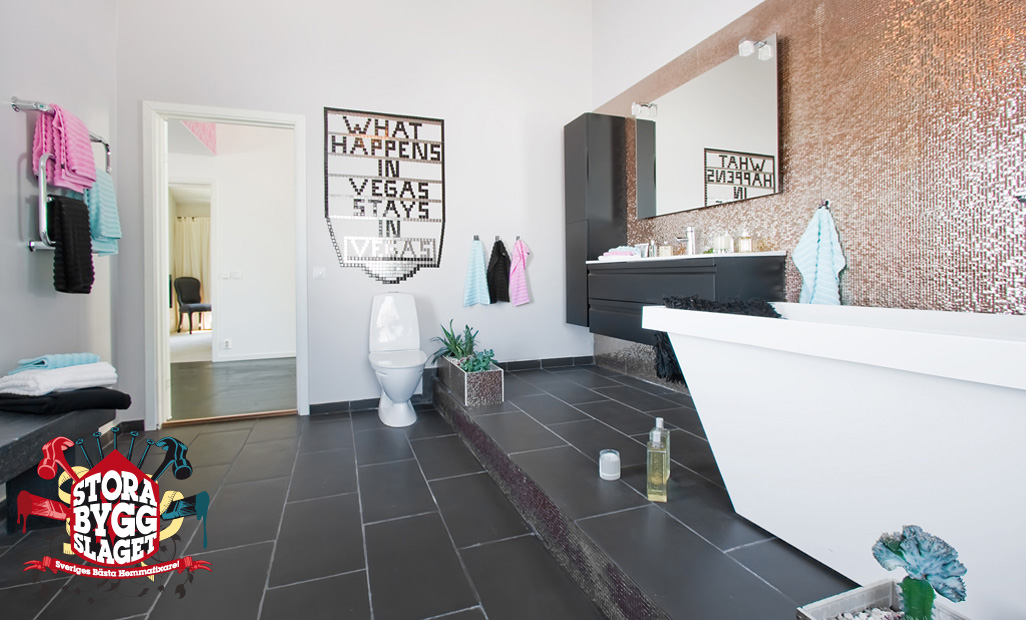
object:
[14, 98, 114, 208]
towel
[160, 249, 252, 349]
chair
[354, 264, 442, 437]
toilet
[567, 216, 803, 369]
vanity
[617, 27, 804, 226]
mirror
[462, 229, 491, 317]
hand towel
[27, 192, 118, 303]
towel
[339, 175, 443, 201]
vegas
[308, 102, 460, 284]
sign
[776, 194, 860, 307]
towel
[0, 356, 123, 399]
towel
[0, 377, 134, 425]
towel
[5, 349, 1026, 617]
floor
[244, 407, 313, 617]
lines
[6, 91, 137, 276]
rack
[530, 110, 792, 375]
cabinet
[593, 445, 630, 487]
candle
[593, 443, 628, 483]
glass holder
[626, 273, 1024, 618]
bath tub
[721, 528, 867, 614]
tile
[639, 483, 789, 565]
tile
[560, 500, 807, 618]
tile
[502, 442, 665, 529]
tile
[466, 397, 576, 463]
tile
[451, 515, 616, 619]
tile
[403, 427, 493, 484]
tile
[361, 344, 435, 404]
bowl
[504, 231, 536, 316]
towel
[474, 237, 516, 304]
towel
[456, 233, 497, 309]
towel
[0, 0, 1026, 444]
wall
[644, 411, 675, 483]
bottle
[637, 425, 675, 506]
bottle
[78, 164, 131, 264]
towel